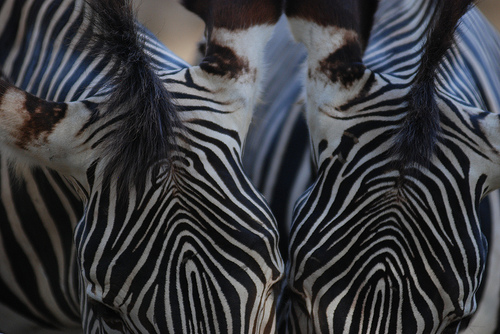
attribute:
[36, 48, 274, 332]
zebra — white, looking, black, staring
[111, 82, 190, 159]
hair — black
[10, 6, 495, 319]
picture — daytime, wildlife, herded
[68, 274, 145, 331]
eyes — black